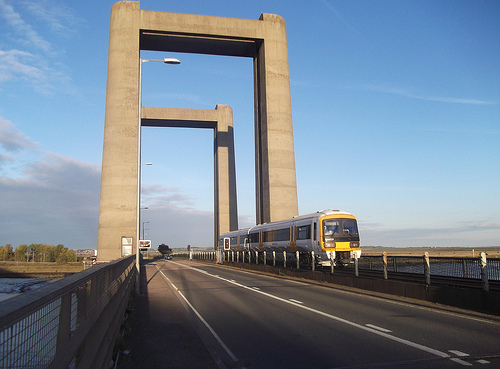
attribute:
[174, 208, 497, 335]
railroad — long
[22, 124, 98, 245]
cloud — white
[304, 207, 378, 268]
windshield — clear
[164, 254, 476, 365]
line — white, long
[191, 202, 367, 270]
train — rolling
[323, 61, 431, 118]
clouds — white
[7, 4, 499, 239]
sky — blue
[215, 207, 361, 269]
train — yellow, white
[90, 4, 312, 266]
arch — tall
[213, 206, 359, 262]
train — rolling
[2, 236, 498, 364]
bridge — tall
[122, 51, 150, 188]
pole — tall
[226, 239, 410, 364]
lines — white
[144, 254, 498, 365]
highway — long